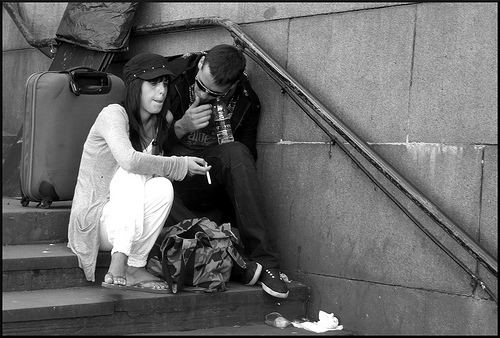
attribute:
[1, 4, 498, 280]
handrail — weathered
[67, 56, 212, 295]
woman — smoking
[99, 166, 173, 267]
pants — white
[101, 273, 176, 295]
flip flops — grey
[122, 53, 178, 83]
hat — black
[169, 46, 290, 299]
man — young, looking down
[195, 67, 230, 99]
sunglasses — black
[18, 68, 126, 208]
suitcase — standing, here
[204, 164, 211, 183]
cigarette — between fingers, white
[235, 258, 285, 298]
shoes — black, white, without laces, sneakers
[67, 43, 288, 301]
people — couple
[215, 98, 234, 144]
bottle — water bottle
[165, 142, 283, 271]
pants — jeans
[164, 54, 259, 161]
jacket — black